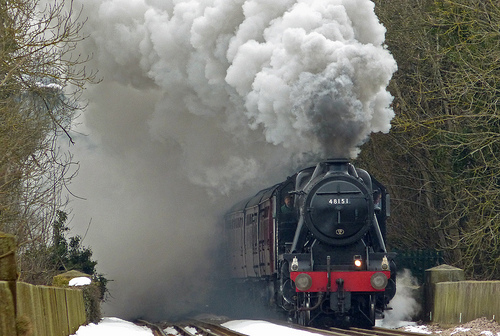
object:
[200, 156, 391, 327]
train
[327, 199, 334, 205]
numbers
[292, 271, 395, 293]
bumper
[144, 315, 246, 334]
tracks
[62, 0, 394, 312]
smoke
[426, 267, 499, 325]
gate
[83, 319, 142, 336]
snow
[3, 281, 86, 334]
fence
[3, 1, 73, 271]
tree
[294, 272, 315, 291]
headlight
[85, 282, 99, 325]
wall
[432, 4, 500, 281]
trees